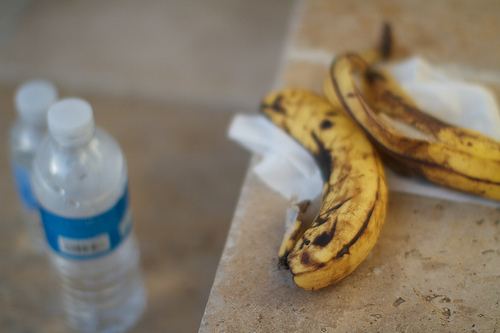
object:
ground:
[0, 0, 267, 80]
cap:
[11, 78, 61, 116]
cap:
[42, 95, 95, 142]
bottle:
[0, 79, 62, 254]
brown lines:
[298, 120, 345, 233]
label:
[33, 183, 131, 264]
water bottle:
[28, 97, 146, 333]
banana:
[259, 83, 389, 291]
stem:
[246, 113, 310, 260]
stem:
[350, 46, 500, 147]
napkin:
[382, 52, 499, 210]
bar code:
[58, 234, 112, 256]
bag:
[225, 109, 329, 203]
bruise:
[299, 124, 344, 155]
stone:
[363, 243, 498, 333]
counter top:
[195, 0, 500, 333]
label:
[8, 167, 35, 207]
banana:
[322, 49, 497, 196]